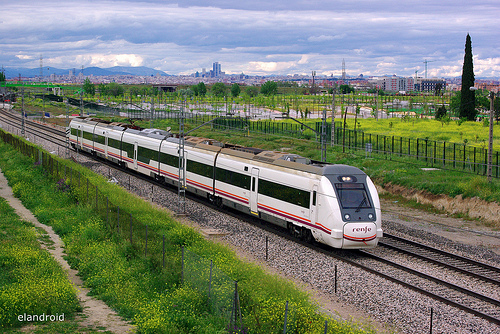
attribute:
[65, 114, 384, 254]
train — windscreen , in the photo., in the photo, long, white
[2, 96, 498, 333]
fence — wired, dirt, metal, iron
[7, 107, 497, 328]
track — ballast , in the picture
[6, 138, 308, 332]
plant — green, in the photo, yellow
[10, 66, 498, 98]
buildings — in the photo, tall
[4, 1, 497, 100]
cloud — skies , in the photo., white, rolling in, gray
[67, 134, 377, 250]
stripe — red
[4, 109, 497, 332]
gravel — gray, black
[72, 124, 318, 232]
window — long, rectangular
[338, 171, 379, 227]
headlight — white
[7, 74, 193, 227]
pole — black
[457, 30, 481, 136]
tree — tall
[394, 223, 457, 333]
line — in the photo, rail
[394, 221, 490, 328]
path — dirt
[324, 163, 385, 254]
front — flat